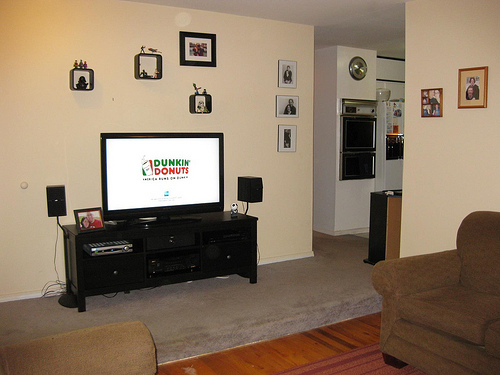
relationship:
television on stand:
[97, 132, 225, 228] [54, 209, 259, 315]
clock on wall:
[347, 55, 368, 82] [338, 42, 378, 238]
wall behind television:
[0, 10, 316, 302] [97, 132, 225, 228]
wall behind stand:
[0, 10, 316, 302] [61, 201, 261, 312]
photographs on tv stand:
[72, 207, 106, 236] [59, 199, 259, 310]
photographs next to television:
[72, 207, 106, 236] [97, 132, 225, 228]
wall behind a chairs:
[398, 1, 497, 259] [369, 210, 499, 375]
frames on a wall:
[71, 29, 299, 153] [0, 10, 316, 302]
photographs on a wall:
[72, 207, 106, 236] [0, 10, 316, 302]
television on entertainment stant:
[77, 84, 261, 239] [48, 196, 280, 318]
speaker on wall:
[46, 184, 67, 218] [0, 0, 313, 303]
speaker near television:
[46, 184, 67, 218] [77, 106, 248, 234]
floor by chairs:
[162, 297, 398, 371] [11, 190, 496, 349]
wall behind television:
[0, 0, 313, 303] [89, 117, 239, 221]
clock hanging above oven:
[347, 55, 368, 82] [338, 106, 379, 179]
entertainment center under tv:
[61, 201, 259, 311] [97, 126, 231, 226]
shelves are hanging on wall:
[72, 51, 215, 111] [0, 10, 316, 302]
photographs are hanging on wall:
[72, 207, 106, 236] [0, 10, 316, 302]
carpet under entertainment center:
[0, 251, 383, 372] [61, 201, 259, 311]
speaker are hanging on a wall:
[46, 184, 67, 218] [0, 10, 316, 302]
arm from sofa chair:
[3, 319, 156, 371] [0, 310, 163, 372]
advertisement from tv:
[139, 150, 192, 187] [93, 122, 229, 220]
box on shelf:
[82, 237, 133, 256] [75, 216, 153, 262]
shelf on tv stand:
[75, 216, 153, 262] [59, 199, 259, 310]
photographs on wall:
[72, 207, 106, 236] [0, 0, 313, 303]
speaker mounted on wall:
[46, 184, 67, 218] [0, 10, 316, 302]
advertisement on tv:
[139, 157, 191, 180] [97, 126, 231, 226]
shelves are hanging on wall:
[63, 49, 217, 119] [0, 10, 316, 302]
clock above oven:
[346, 47, 374, 87] [329, 103, 380, 182]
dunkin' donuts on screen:
[138, 155, 190, 181] [101, 130, 224, 219]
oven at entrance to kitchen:
[336, 96, 375, 181] [315, 44, 402, 236]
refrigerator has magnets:
[376, 97, 402, 191] [387, 99, 401, 134]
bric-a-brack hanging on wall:
[67, 44, 213, 114] [0, 10, 316, 302]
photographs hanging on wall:
[72, 207, 106, 236] [0, 10, 316, 302]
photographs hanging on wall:
[275, 59, 299, 151] [0, 10, 316, 302]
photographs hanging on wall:
[417, 64, 487, 115] [398, 1, 497, 259]